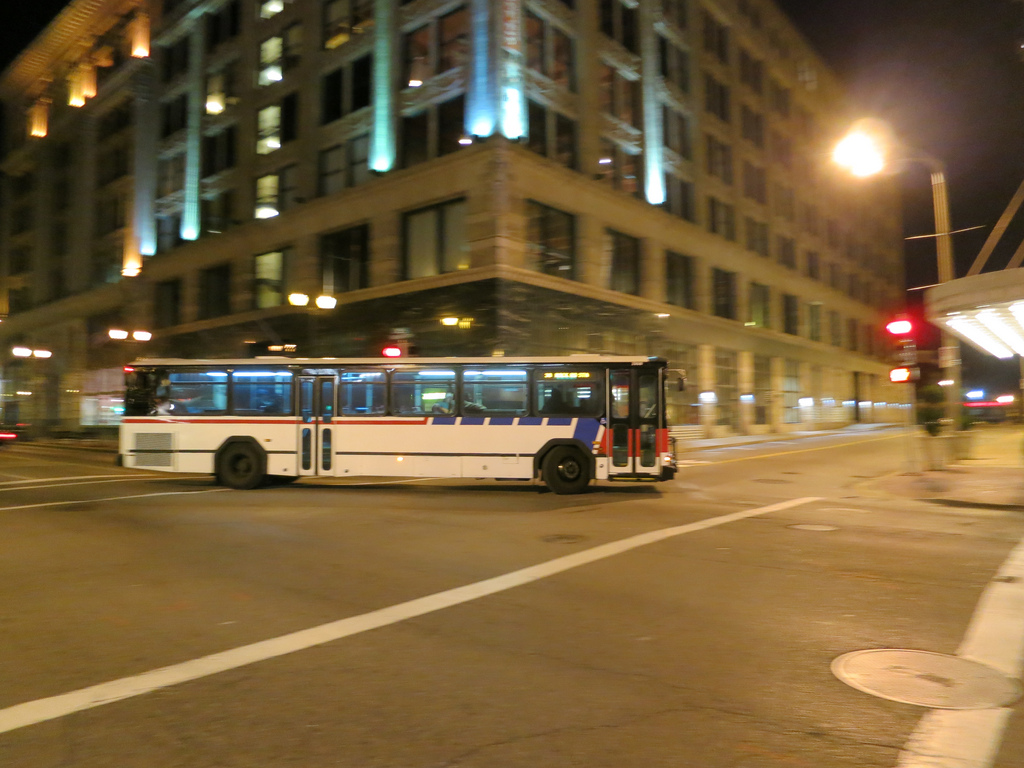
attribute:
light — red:
[876, 305, 927, 376]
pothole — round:
[823, 626, 1021, 718]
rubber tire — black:
[532, 433, 605, 507]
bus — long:
[117, 345, 690, 500]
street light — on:
[819, 115, 979, 467]